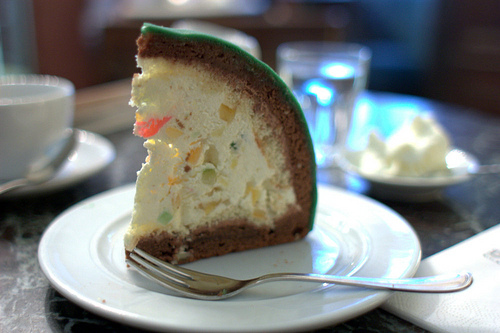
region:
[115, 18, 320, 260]
A large slice of cake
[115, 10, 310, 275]
A yellow cake slice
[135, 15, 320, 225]
A slice of cake with green icing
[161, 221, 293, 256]
A brown layer around cake slice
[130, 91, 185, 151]
A pink fruit or candy in slice of cake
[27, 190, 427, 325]
A white dessert plate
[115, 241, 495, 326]
A silver colored fork on white plate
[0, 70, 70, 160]
A white coffee cup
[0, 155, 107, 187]
A white saucer with a spoon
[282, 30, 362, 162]
A clear glass of water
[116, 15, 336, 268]
Cake on a plate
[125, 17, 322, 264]
Cake on a white plate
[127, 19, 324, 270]
Cake on a round plate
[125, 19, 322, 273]
Cake on a round white plate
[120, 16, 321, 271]
Slice of cake on a plate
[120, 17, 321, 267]
Slice of cake on a white plate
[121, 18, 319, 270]
Slice of cake on a round plate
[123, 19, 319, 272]
Slice of cake on a round white plate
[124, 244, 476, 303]
Fork on a plate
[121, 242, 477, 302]
Fork on a white plate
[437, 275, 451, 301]
part of a fork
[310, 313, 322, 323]
part of a plate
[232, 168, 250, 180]
side of a cake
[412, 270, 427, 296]
edge of a fork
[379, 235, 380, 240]
edge of a plate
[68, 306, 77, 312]
part of a table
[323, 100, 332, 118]
part of a glass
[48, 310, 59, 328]
side of a table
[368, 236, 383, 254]
edge of a plate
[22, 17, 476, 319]
a piece of cake on a plate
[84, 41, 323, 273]
the cake is green white and brown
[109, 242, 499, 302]
a fork on the plate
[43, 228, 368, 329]
the plate is white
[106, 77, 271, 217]
there is some kind of fruit in the cake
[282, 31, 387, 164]
a blurry glass of water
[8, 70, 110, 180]
a white bowl in the background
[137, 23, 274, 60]
green icing on the cake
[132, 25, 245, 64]
this a chocolate cake with green icing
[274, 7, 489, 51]
the background is blurry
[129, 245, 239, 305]
it is the top of the fork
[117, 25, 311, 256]
a piece of cake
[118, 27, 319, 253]
half a piece of cake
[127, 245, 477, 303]
a silver fork on the plate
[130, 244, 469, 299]
it is a silver fork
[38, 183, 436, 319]
a white plate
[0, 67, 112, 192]
a plate and a cup in the background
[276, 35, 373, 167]
a glass of water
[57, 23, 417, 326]
a piece of cake on the plate with a fork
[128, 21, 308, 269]
cake piece